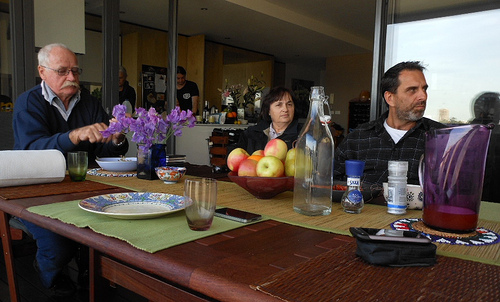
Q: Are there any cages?
A: No, there are no cages.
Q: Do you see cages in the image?
A: No, there are no cages.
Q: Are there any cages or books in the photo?
A: No, there are no cages or books.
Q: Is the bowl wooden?
A: Yes, the bowl is wooden.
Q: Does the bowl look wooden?
A: Yes, the bowl is wooden.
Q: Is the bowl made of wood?
A: Yes, the bowl is made of wood.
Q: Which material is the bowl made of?
A: The bowl is made of wood.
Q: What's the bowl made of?
A: The bowl is made of wood.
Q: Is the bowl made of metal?
A: No, the bowl is made of wood.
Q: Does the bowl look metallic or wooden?
A: The bowl is wooden.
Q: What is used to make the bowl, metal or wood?
A: The bowl is made of wood.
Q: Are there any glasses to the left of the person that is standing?
A: Yes, there are glasses to the left of the person.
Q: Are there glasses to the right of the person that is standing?
A: No, the glasses are to the left of the person.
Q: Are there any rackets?
A: No, there are no rackets.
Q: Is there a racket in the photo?
A: No, there are no rackets.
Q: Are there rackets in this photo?
A: No, there are no rackets.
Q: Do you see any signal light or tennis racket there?
A: No, there are no rackets or traffic lights.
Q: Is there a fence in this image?
A: No, there are no fences.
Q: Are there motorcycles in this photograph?
A: No, there are no motorcycles.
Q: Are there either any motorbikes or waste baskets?
A: No, there are no motorbikes or waste baskets.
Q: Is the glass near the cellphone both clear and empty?
A: Yes, the glass is clear and empty.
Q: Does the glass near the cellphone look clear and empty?
A: Yes, the glass is clear and empty.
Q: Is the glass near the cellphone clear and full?
A: No, the glass is clear but empty.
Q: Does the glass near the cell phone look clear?
A: Yes, the glass is clear.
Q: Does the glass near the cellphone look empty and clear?
A: Yes, the glass is empty and clear.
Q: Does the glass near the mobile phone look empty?
A: Yes, the glass is empty.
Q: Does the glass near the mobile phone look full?
A: No, the glass is empty.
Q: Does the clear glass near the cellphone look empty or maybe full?
A: The glass is empty.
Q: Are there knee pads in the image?
A: No, there are no knee pads.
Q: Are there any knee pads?
A: No, there are no knee pads.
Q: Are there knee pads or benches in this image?
A: No, there are no knee pads or benches.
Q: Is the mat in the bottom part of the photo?
A: Yes, the mat is in the bottom of the image.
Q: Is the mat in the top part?
A: No, the mat is in the bottom of the image.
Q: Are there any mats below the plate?
A: Yes, there is a mat below the plate.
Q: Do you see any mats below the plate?
A: Yes, there is a mat below the plate.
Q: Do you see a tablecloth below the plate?
A: No, there is a mat below the plate.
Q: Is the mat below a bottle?
A: No, the mat is below the plate.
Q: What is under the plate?
A: The mat is under the plate.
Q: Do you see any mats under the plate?
A: Yes, there is a mat under the plate.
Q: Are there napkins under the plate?
A: No, there is a mat under the plate.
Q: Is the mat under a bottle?
A: No, the mat is under a plate.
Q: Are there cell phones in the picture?
A: Yes, there is a cell phone.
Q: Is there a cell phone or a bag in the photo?
A: Yes, there is a cell phone.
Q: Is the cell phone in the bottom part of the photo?
A: Yes, the cell phone is in the bottom of the image.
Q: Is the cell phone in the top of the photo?
A: No, the cell phone is in the bottom of the image.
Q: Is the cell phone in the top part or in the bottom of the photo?
A: The cell phone is in the bottom of the image.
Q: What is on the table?
A: The cellphone is on the table.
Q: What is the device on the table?
A: The device is a cell phone.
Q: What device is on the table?
A: The device is a cell phone.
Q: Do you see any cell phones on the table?
A: Yes, there is a cell phone on the table.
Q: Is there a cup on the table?
A: No, there is a cell phone on the table.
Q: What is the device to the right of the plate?
A: The device is a cell phone.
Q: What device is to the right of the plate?
A: The device is a cell phone.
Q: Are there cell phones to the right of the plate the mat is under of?
A: Yes, there is a cell phone to the right of the plate.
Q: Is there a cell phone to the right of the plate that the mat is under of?
A: Yes, there is a cell phone to the right of the plate.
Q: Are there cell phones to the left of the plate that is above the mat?
A: No, the cell phone is to the right of the plate.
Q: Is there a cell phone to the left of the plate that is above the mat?
A: No, the cell phone is to the right of the plate.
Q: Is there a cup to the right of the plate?
A: No, there is a cell phone to the right of the plate.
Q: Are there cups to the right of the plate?
A: No, there is a cell phone to the right of the plate.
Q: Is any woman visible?
A: Yes, there is a woman.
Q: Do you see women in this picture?
A: Yes, there is a woman.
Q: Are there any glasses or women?
A: Yes, there is a woman.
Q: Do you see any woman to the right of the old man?
A: Yes, there is a woman to the right of the man.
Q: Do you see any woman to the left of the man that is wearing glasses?
A: No, the woman is to the right of the man.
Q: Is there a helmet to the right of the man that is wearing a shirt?
A: No, there is a woman to the right of the man.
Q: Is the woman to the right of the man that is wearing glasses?
A: Yes, the woman is to the right of the man.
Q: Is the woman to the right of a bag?
A: No, the woman is to the right of the man.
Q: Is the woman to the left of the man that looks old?
A: No, the woman is to the right of the man.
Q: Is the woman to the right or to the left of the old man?
A: The woman is to the right of the man.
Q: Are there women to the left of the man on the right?
A: Yes, there is a woman to the left of the man.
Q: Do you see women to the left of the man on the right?
A: Yes, there is a woman to the left of the man.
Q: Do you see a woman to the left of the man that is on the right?
A: Yes, there is a woman to the left of the man.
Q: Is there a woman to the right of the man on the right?
A: No, the woman is to the left of the man.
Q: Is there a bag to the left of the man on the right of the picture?
A: No, there is a woman to the left of the man.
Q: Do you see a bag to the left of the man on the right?
A: No, there is a woman to the left of the man.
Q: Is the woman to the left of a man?
A: Yes, the woman is to the left of a man.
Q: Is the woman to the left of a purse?
A: No, the woman is to the left of a man.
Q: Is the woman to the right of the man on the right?
A: No, the woman is to the left of the man.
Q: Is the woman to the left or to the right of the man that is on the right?
A: The woman is to the left of the man.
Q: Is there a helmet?
A: No, there are no helmets.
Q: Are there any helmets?
A: No, there are no helmets.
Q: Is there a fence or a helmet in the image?
A: No, there are no helmets or fences.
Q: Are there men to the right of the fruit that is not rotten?
A: Yes, there is a man to the right of the fruit.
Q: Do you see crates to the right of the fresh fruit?
A: No, there is a man to the right of the fruit.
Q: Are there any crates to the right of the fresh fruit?
A: No, there is a man to the right of the fruit.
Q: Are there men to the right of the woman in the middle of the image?
A: Yes, there is a man to the right of the woman.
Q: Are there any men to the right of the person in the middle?
A: Yes, there is a man to the right of the woman.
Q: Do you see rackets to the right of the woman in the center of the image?
A: No, there is a man to the right of the woman.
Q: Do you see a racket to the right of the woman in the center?
A: No, there is a man to the right of the woman.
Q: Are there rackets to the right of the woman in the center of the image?
A: No, there is a man to the right of the woman.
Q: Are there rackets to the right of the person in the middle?
A: No, there is a man to the right of the woman.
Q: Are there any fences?
A: No, there are no fences.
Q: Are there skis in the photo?
A: No, there are no skis.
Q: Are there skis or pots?
A: No, there are no skis or pots.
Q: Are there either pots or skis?
A: No, there are no skis or pots.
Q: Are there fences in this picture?
A: No, there are no fences.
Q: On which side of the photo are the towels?
A: The towels are on the left of the image.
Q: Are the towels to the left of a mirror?
A: No, the towels are to the left of the vase.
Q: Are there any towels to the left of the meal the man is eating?
A: Yes, there are towels to the left of the meal.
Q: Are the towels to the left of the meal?
A: Yes, the towels are to the left of the meal.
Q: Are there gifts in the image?
A: No, there are no gifts.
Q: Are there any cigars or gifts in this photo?
A: No, there are no gifts or cigars.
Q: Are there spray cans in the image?
A: No, there are no spray cans.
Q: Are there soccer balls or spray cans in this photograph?
A: No, there are no spray cans or soccer balls.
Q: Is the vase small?
A: Yes, the vase is small.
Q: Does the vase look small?
A: Yes, the vase is small.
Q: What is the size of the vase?
A: The vase is small.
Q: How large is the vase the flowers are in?
A: The vase is small.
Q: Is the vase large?
A: No, the vase is small.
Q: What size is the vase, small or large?
A: The vase is small.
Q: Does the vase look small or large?
A: The vase is small.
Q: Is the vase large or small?
A: The vase is small.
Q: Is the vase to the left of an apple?
A: Yes, the vase is to the left of an apple.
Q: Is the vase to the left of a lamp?
A: No, the vase is to the left of an apple.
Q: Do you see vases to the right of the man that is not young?
A: Yes, there is a vase to the right of the man.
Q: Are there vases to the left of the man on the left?
A: No, the vase is to the right of the man.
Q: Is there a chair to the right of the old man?
A: No, there is a vase to the right of the man.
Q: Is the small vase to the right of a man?
A: Yes, the vase is to the right of a man.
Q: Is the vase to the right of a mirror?
A: No, the vase is to the right of a man.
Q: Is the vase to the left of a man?
A: No, the vase is to the right of a man.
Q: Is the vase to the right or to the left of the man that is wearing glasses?
A: The vase is to the right of the man.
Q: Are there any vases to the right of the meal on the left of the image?
A: Yes, there is a vase to the right of the meal.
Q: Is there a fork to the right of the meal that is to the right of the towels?
A: No, there is a vase to the right of the meal.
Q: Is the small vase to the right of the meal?
A: Yes, the vase is to the right of the meal.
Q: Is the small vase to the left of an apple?
A: Yes, the vase is to the left of an apple.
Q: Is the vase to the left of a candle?
A: No, the vase is to the left of an apple.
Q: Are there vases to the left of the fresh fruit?
A: Yes, there is a vase to the left of the fruit.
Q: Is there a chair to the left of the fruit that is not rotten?
A: No, there is a vase to the left of the fruit.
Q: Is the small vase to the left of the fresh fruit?
A: Yes, the vase is to the left of the fruit.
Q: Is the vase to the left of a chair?
A: No, the vase is to the left of the fruit.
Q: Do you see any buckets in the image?
A: No, there are no buckets.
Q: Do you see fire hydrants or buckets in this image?
A: No, there are no buckets or fire hydrants.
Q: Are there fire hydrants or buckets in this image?
A: No, there are no buckets or fire hydrants.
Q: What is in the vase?
A: The flowers are in the vase.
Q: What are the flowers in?
A: The flowers are in the vase.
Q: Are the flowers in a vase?
A: Yes, the flowers are in a vase.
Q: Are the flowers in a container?
A: No, the flowers are in a vase.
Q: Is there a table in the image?
A: Yes, there is a table.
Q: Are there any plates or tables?
A: Yes, there is a table.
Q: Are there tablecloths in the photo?
A: No, there are no tablecloths.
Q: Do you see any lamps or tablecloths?
A: No, there are no tablecloths or lamps.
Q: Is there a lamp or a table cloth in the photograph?
A: No, there are no tablecloths or lamps.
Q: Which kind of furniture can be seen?
A: The furniture is a table.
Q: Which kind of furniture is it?
A: The piece of furniture is a table.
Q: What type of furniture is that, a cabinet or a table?
A: That is a table.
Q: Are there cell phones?
A: Yes, there is a cell phone.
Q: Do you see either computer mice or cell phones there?
A: Yes, there is a cell phone.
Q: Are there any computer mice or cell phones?
A: Yes, there is a cell phone.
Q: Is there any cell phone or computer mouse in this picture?
A: Yes, there is a cell phone.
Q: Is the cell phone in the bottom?
A: Yes, the cell phone is in the bottom of the image.